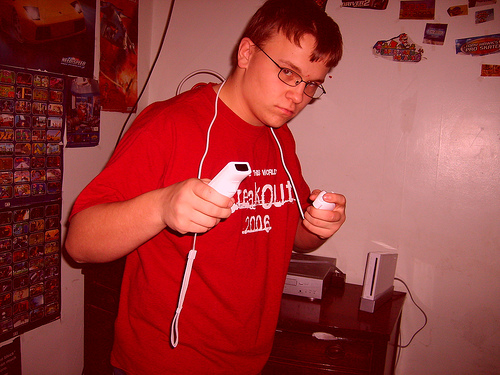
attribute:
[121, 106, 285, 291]
tshirt — red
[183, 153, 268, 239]
controller — white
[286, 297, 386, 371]
drawer — brown, wooen, wooden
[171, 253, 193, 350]
strap — white